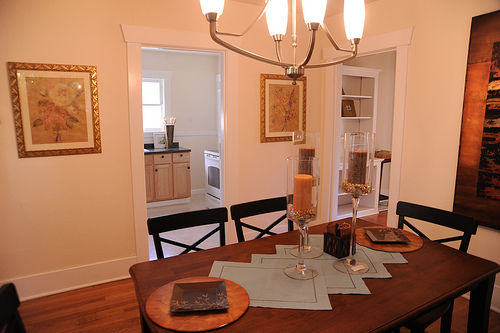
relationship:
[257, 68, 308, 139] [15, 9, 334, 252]
artwork on wall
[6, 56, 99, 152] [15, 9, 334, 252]
artwork on wall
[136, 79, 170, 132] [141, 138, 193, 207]
window on top of counter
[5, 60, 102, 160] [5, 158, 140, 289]
artwork on wall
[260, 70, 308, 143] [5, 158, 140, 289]
artwork on wall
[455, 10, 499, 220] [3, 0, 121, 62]
painting on wall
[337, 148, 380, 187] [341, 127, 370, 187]
candle in vase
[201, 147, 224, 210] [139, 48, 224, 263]
oven in kitchen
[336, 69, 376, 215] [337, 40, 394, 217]
bookcase in room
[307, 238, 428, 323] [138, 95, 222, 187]
counter in kitchen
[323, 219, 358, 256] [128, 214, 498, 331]
basket on table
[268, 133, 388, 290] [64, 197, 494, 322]
candle holders on table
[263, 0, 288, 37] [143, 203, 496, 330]
bulb over table